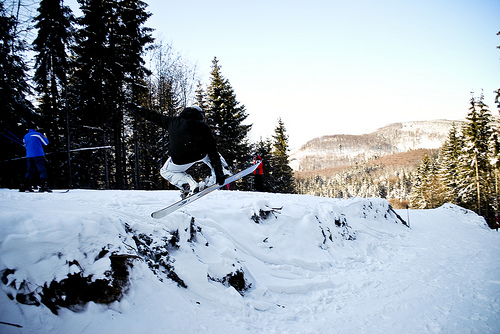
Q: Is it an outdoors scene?
A: Yes, it is outdoors.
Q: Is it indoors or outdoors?
A: It is outdoors.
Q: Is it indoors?
A: No, it is outdoors.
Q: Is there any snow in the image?
A: Yes, there is snow.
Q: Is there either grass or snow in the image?
A: Yes, there is snow.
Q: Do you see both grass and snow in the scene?
A: No, there is snow but no grass.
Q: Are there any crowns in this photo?
A: No, there are no crowns.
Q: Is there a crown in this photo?
A: No, there are no crowns.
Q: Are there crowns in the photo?
A: No, there are no crowns.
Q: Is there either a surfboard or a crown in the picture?
A: No, there are no crowns or surfboards.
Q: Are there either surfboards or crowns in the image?
A: No, there are no crowns or surfboards.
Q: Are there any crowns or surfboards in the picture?
A: No, there are no crowns or surfboards.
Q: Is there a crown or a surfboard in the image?
A: No, there are no crowns or surfboards.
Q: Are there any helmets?
A: No, there are no helmets.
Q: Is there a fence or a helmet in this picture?
A: No, there are no helmets or fences.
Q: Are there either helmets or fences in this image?
A: No, there are no helmets or fences.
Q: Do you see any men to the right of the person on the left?
A: Yes, there is a man to the right of the person.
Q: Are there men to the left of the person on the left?
A: No, the man is to the right of the person.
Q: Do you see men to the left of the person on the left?
A: No, the man is to the right of the person.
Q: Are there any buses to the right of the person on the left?
A: No, there is a man to the right of the person.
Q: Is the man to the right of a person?
A: Yes, the man is to the right of a person.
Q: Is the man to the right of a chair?
A: No, the man is to the right of a person.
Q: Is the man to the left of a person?
A: No, the man is to the right of a person.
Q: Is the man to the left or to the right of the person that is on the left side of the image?
A: The man is to the right of the person.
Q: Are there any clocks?
A: No, there are no clocks.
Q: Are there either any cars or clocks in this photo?
A: No, there are no clocks or cars.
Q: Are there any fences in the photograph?
A: No, there are no fences.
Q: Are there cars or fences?
A: No, there are no fences or cars.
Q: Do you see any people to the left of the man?
A: Yes, there is a person to the left of the man.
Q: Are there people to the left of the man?
A: Yes, there is a person to the left of the man.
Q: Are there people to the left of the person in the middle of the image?
A: Yes, there is a person to the left of the man.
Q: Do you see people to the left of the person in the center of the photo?
A: Yes, there is a person to the left of the man.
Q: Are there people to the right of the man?
A: No, the person is to the left of the man.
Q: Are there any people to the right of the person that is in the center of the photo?
A: No, the person is to the left of the man.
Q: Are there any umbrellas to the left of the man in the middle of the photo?
A: No, there is a person to the left of the man.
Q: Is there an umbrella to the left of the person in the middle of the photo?
A: No, there is a person to the left of the man.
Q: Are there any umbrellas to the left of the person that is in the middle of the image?
A: No, there is a person to the left of the man.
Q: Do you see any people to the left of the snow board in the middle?
A: Yes, there is a person to the left of the snowboard.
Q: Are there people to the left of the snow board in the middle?
A: Yes, there is a person to the left of the snowboard.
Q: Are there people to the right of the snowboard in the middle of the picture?
A: No, the person is to the left of the snowboard.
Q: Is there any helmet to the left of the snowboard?
A: No, there is a person to the left of the snowboard.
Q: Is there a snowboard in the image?
A: Yes, there is a snowboard.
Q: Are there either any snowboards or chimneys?
A: Yes, there is a snowboard.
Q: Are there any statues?
A: No, there are no statues.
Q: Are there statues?
A: No, there are no statues.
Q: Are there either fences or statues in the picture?
A: No, there are no statues or fences.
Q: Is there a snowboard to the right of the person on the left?
A: Yes, there is a snowboard to the right of the person.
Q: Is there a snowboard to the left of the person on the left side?
A: No, the snowboard is to the right of the person.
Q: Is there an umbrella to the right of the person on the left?
A: No, there is a snowboard to the right of the person.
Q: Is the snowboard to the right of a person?
A: Yes, the snowboard is to the right of a person.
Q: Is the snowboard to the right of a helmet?
A: No, the snowboard is to the right of a person.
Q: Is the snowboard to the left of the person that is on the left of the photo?
A: No, the snowboard is to the right of the person.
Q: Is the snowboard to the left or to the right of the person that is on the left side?
A: The snowboard is to the right of the person.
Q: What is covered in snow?
A: The mountain is covered in snow.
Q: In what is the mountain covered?
A: The mountain is covered in snow.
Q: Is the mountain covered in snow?
A: Yes, the mountain is covered in snow.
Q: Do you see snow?
A: Yes, there is snow.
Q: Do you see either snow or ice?
A: Yes, there is snow.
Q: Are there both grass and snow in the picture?
A: No, there is snow but no grass.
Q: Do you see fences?
A: No, there are no fences.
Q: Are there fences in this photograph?
A: No, there are no fences.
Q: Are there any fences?
A: No, there are no fences.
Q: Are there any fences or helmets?
A: No, there are no fences or helmets.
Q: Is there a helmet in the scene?
A: No, there are no helmets.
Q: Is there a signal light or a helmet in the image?
A: No, there are no helmets or traffic lights.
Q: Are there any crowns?
A: No, there are no crowns.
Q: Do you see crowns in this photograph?
A: No, there are no crowns.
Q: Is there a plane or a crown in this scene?
A: No, there are no crowns or airplanes.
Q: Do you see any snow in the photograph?
A: Yes, there is snow.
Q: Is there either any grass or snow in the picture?
A: Yes, there is snow.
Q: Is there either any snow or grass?
A: Yes, there is snow.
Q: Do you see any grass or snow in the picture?
A: Yes, there is snow.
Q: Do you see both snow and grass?
A: No, there is snow but no grass.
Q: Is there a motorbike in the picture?
A: No, there are no motorcycles.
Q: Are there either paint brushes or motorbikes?
A: No, there are no motorbikes or paint brushes.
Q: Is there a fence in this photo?
A: No, there are no fences.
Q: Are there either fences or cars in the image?
A: No, there are no fences or cars.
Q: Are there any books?
A: No, there are no books.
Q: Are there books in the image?
A: No, there are no books.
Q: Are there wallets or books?
A: No, there are no books or wallets.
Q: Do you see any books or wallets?
A: No, there are no books or wallets.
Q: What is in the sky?
A: The clouds are in the sky.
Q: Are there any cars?
A: No, there are no cars.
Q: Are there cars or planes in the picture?
A: No, there are no cars or planes.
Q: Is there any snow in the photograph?
A: Yes, there is snow.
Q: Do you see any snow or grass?
A: Yes, there is snow.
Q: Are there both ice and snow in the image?
A: No, there is snow but no ice.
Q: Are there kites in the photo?
A: No, there are no kites.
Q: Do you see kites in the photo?
A: No, there are no kites.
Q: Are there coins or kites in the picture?
A: No, there are no kites or coins.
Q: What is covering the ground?
A: The snow is covering the ground.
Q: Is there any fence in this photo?
A: No, there are no fences.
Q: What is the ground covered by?
A: The ground is covered by the snow.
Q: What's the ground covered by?
A: The ground is covered by the snow.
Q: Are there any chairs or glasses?
A: No, there are no glasses or chairs.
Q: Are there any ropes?
A: No, there are no ropes.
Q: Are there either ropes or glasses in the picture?
A: No, there are no ropes or glasses.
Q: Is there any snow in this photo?
A: Yes, there is snow.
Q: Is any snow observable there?
A: Yes, there is snow.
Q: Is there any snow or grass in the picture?
A: Yes, there is snow.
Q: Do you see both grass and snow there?
A: No, there is snow but no grass.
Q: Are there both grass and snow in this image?
A: No, there is snow but no grass.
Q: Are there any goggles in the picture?
A: No, there are no goggles.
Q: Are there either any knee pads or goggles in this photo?
A: No, there are no goggles or knee pads.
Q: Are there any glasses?
A: No, there are no glasses.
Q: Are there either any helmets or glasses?
A: No, there are no glasses or helmets.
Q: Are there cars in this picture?
A: No, there are no cars.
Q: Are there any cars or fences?
A: No, there are no cars or fences.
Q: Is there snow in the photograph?
A: Yes, there is snow.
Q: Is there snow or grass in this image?
A: Yes, there is snow.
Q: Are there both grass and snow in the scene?
A: No, there is snow but no grass.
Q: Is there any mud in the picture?
A: No, there is no mud.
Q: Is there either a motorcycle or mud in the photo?
A: No, there are no mud or motorcycles.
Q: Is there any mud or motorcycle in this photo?
A: No, there are no mud or motorcycles.